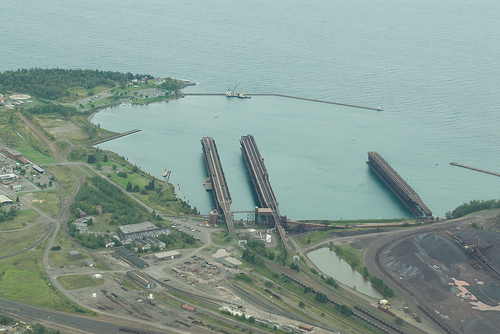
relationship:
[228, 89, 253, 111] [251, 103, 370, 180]
boat in water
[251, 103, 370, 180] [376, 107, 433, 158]
water has opening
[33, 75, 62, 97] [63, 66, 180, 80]
trees near shore